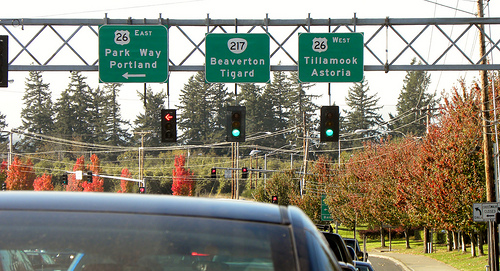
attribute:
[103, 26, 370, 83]
signs — green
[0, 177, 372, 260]
traffic — moving, driving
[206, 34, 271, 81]
sign — green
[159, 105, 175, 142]
signal — red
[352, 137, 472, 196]
leaves — orange, red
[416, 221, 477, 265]
grass — green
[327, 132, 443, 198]
park — white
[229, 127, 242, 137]
light — green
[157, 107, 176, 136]
light — red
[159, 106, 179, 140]
sign — pointing left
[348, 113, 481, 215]
trees — on the side, red, orange, colorful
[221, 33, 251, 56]
number — 217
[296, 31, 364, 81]
sign — green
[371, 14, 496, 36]
pole — grey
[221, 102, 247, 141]
traffic light — green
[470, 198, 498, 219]
sign — black, white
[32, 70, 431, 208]
pines — tall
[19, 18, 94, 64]
support bars — grey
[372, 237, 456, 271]
sidewalk — next to road